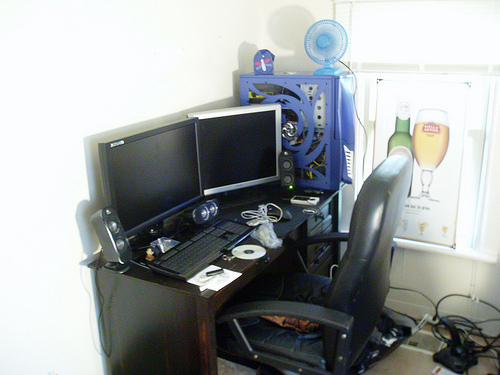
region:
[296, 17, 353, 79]
small blue desk fan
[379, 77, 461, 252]
Stella Artois beef poster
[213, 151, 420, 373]
black desk chair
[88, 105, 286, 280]
computer with two monitors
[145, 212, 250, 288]
black computer keyboard on desk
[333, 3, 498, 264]
window with white curtains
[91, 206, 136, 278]
small black computer speaker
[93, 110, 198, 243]
black desktop computer monitor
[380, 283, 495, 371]
extension cords on ground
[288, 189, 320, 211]
white cellphone on desk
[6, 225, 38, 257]
white paint on wall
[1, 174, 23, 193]
white paint on wall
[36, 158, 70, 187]
white paint on wall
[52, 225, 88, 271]
white paint on wall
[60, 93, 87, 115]
white paint on wall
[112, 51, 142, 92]
white paint on wall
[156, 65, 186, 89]
white paint on wall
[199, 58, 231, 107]
white paint on wall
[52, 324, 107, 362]
white paint on wall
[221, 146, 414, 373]
a black desk chair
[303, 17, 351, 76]
a small blue fan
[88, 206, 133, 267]
a speaker next to a monitor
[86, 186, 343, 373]
a dark brown wood desk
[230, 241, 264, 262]
a disc on a desk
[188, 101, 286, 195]
a white monitor on a desk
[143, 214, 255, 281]
a black keyboard on a desk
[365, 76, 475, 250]
a picture in a window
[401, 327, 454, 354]
a vent on the floor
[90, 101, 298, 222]
double monitor setup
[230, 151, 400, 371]
black office chair with arms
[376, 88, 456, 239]
stella artois beer poster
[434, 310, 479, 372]
black video game controller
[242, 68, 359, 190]
purple desktop computer case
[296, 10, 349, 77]
small blue fan on top of computer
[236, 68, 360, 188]
fancy pattern purple computer case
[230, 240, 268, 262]
optical disc sitting on desk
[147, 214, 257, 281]
black keyboard with number pad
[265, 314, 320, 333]
something orange on the chair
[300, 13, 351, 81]
a small blue fan by the window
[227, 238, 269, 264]
a cd laying on the desk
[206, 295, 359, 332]
the arm of a black chair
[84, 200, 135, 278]
a small computer speaker on the desk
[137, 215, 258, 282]
a keyboard to the computer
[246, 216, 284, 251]
a rolled up piece of plastic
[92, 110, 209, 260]
a screen to the computer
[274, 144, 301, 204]
a small black computer speaker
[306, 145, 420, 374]
the back to a computer chair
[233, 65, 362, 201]
a big blue computer tower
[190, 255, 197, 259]
A key on a keyboard.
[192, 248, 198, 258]
A key on a keyboard.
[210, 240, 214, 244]
A key on a keyboard.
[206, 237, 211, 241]
A key on a keyboard.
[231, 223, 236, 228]
A key on a keyboard.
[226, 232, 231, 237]
A key on a keyboard.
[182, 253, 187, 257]
A key on a keyboard.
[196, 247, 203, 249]
A key on a keyboard.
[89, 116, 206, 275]
dark silver speaker next to black monitor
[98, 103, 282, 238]
black monitor next to white monitor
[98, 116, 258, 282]
black monitor behind black keyboard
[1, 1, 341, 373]
white painted wall behind dark wooden desk